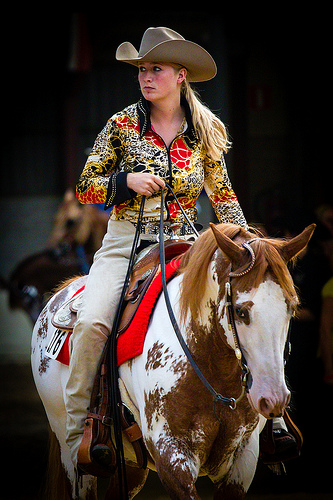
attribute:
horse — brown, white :
[8, 222, 328, 489]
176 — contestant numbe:
[46, 329, 65, 360]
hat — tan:
[113, 12, 225, 82]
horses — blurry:
[45, 187, 108, 264]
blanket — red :
[50, 244, 194, 377]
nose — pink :
[249, 389, 297, 418]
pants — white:
[62, 214, 136, 446]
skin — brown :
[45, 270, 266, 426]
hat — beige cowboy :
[115, 25, 217, 82]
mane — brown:
[173, 201, 298, 298]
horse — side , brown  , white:
[32, 222, 316, 493]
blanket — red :
[53, 259, 179, 367]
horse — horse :
[21, 216, 305, 498]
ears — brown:
[208, 219, 313, 262]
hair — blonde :
[166, 72, 260, 150]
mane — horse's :
[183, 233, 218, 311]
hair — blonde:
[170, 64, 232, 161]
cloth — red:
[120, 249, 182, 366]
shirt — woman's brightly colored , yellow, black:
[70, 95, 255, 245]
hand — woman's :
[125, 168, 166, 199]